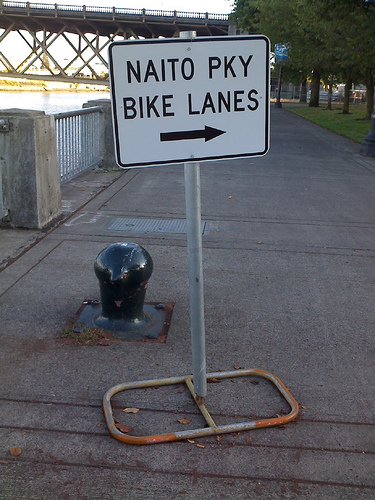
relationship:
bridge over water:
[10, 8, 319, 87] [19, 89, 64, 112]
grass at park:
[314, 109, 363, 128] [276, 1, 372, 148]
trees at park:
[282, 0, 374, 121] [276, 1, 372, 148]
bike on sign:
[88, 90, 188, 117] [65, 33, 361, 193]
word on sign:
[184, 91, 259, 116] [77, 29, 302, 182]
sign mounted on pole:
[107, 32, 270, 162] [185, 163, 208, 397]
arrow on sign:
[158, 118, 230, 146] [104, 33, 278, 171]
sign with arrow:
[107, 32, 270, 162] [152, 115, 230, 153]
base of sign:
[99, 361, 303, 446] [107, 32, 270, 162]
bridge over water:
[10, 8, 319, 87] [30, 89, 75, 112]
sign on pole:
[107, 32, 270, 162] [182, 162, 208, 395]